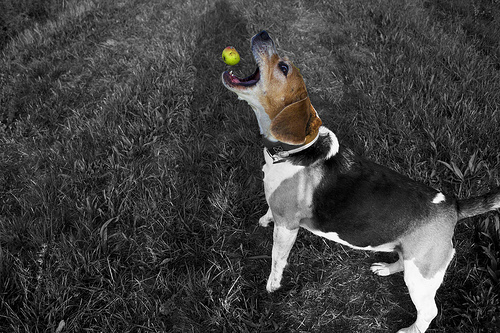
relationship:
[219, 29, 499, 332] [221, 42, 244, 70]
dog catching fruit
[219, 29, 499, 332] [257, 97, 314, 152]
dog has ear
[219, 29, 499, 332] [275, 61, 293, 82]
dog has eye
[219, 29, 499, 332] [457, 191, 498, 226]
dog has tail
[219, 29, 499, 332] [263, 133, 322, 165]
dog has collar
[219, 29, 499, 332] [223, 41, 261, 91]
dog has mouth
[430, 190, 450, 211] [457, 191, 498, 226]
spot on top of tail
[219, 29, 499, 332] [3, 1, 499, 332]
dog on top of grass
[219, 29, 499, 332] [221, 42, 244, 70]
dog trying to catch fruit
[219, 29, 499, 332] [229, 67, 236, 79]
dog has tooth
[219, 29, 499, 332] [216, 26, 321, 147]
dog has head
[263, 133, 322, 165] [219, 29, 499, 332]
collar on neck of dog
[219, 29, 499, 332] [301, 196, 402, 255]
dog has belly